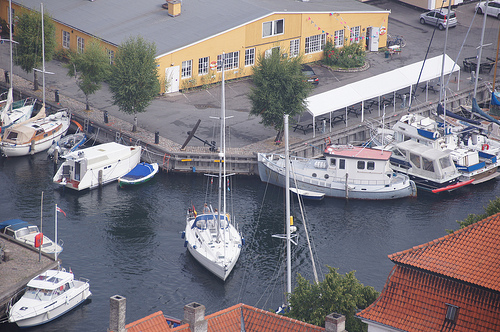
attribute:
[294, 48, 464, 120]
tent — white 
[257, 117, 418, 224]
fishing boat — large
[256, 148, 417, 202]
boat — white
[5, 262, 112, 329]
boat — white, docked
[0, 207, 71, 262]
boat — white, docked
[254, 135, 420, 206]
boat — white, docked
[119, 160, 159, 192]
boat — white, docked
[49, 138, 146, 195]
boat — white, docked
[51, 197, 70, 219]
flag — Red , white 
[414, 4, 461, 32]
suv — white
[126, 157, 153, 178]
tarp — blue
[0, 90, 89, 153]
boat — docked, white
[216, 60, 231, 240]
mast — White 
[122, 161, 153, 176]
cover — blue 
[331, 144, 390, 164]
roof — Red 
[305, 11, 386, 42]
flags — Colored 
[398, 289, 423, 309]
tiles — red 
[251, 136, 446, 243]
boat — large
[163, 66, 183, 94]
door — White 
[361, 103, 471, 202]
boat — white, docked